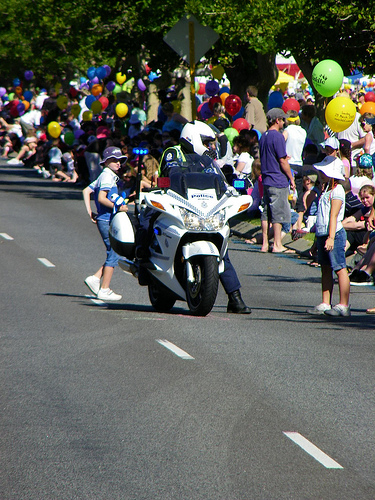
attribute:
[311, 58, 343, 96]
balloon — black, green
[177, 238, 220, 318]
wheel — black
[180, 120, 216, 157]
helmet — white, motorcycle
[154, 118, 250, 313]
officer — police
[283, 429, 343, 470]
line — white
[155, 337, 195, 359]
line — white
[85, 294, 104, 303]
line — white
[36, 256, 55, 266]
line — white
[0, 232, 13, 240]
line — white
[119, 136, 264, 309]
motorcycle — white, black, police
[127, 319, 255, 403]
line — white, furthest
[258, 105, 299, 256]
man — young, wearing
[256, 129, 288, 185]
shirt — purple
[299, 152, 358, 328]
girl — standing, young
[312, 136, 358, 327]
child — small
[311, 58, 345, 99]
balloon — large, green, above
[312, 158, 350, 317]
girl — close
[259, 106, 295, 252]
man — standing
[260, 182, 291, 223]
shorts — black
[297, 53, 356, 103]
balloon — black, green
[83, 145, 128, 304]
little girl — walking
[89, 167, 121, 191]
shirt — blue, white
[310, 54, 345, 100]
balloon — green, black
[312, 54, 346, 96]
balloon — green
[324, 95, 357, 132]
balloon — yellow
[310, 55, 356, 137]
balloons — green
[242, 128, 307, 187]
shirt — purple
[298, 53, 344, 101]
balloon — green, black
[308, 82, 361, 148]
balloon — yellow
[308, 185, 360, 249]
shirt — white